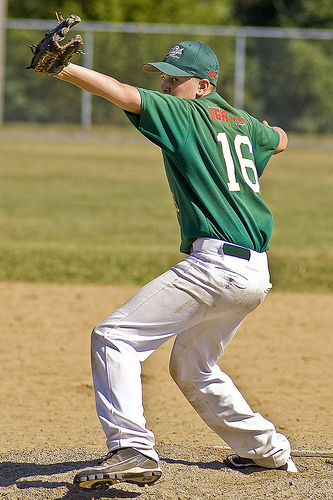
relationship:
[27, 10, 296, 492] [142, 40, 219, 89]
boy wearing hat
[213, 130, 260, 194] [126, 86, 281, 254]
number on back of shirt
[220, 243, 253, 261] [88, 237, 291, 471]
belt around pants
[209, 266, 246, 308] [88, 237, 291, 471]
pocket on back of pants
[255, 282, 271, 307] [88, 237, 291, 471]
pocket on back of pants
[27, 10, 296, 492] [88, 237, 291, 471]
boy wearing pants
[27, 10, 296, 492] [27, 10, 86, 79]
boy wearing glove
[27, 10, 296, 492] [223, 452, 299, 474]
boy has foot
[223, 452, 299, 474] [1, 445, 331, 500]
foot on top of pitcher mound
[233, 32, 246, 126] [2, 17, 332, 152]
pole part of fence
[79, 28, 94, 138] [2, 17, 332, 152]
pole part of fence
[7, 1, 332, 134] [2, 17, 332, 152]
trees behind fence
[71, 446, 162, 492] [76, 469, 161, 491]
shoe has sole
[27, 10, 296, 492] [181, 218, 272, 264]
boy has waist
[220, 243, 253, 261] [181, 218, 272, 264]
belt around waist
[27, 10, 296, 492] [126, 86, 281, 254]
boy wearing shirt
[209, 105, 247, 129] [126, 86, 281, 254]
sponsor name on back of shirt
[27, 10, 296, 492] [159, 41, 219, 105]
boy has head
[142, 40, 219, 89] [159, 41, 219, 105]
hat on top of head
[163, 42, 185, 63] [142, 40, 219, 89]
logo on front of hat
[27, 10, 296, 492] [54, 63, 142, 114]
boy has arm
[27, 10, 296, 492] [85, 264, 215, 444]
boy has leg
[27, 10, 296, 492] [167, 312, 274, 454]
boy has leg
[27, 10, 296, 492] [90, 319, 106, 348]
boy has knee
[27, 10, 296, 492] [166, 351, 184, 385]
boy has knee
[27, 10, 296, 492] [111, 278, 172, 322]
boy has thigh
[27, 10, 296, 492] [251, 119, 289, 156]
boy has arm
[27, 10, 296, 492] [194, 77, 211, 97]
boy has ear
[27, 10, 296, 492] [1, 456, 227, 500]
boy has shadow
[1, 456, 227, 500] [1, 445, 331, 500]
shadow cast on pitcher mound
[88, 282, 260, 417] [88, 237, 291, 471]
dirt stains rubbed on pants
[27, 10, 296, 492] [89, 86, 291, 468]
boy wearing uniform